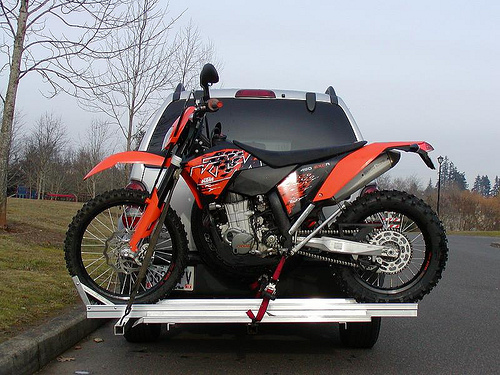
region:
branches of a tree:
[90, 19, 152, 94]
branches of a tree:
[31, 9, 62, 77]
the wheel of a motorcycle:
[333, 185, 448, 301]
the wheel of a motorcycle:
[59, 194, 184, 305]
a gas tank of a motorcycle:
[187, 146, 253, 201]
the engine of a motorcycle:
[220, 200, 261, 253]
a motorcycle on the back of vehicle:
[59, 62, 444, 337]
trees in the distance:
[31, 131, 76, 196]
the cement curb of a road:
[16, 310, 85, 368]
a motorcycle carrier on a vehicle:
[60, 279, 428, 340]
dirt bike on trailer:
[77, 70, 438, 302]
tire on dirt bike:
[68, 189, 179, 311]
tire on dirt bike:
[329, 177, 442, 299]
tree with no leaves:
[42, 125, 54, 198]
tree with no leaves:
[71, 150, 86, 198]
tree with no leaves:
[11, 149, 30, 199]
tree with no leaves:
[75, 119, 99, 195]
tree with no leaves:
[6, 145, 21, 187]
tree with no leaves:
[36, 173, 50, 200]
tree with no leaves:
[63, 169, 80, 201]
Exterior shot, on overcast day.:
[3, 1, 493, 366]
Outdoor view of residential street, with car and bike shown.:
[2, 2, 492, 362]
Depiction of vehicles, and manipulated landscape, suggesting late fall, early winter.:
[3, 6, 496, 368]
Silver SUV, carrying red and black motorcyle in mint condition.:
[92, 83, 437, 339]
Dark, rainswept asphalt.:
[453, 246, 496, 357]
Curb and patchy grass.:
[13, 198, 88, 371]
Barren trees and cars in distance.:
[5, 13, 156, 208]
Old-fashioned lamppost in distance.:
[435, 150, 451, 232]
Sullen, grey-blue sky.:
[260, 11, 465, 91]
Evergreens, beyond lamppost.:
[448, 164, 494, 196]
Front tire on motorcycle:
[59, 183, 196, 313]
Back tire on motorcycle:
[327, 187, 453, 310]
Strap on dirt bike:
[227, 255, 302, 335]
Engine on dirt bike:
[200, 180, 281, 270]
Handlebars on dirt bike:
[180, 92, 227, 118]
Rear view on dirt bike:
[190, 60, 225, 95]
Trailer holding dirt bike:
[60, 262, 445, 348]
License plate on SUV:
[138, 261, 200, 295]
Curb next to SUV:
[0, 283, 130, 373]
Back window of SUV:
[141, 94, 365, 192]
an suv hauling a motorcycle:
[20, 64, 489, 359]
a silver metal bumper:
[175, 305, 365, 326]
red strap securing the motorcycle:
[256, 267, 280, 330]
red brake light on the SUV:
[237, 83, 282, 103]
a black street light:
[434, 151, 446, 211]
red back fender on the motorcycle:
[342, 145, 381, 173]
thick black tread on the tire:
[406, 194, 431, 216]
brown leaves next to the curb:
[58, 334, 103, 367]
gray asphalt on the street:
[439, 291, 485, 373]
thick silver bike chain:
[299, 247, 337, 262]